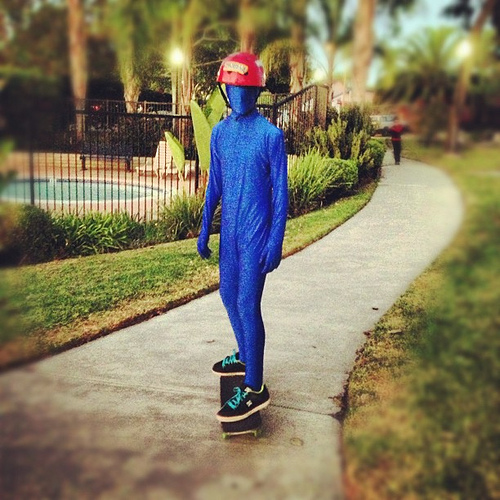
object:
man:
[197, 49, 288, 422]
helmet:
[216, 51, 266, 88]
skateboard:
[220, 376, 262, 441]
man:
[389, 116, 403, 164]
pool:
[2, 179, 161, 204]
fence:
[2, 83, 330, 222]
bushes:
[2, 104, 378, 267]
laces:
[227, 387, 248, 410]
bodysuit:
[197, 112, 287, 390]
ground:
[1, 144, 496, 500]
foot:
[215, 383, 270, 422]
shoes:
[215, 383, 272, 422]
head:
[224, 53, 261, 116]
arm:
[267, 129, 288, 238]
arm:
[202, 128, 220, 229]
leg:
[236, 240, 267, 386]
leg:
[218, 246, 247, 359]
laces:
[221, 348, 235, 366]